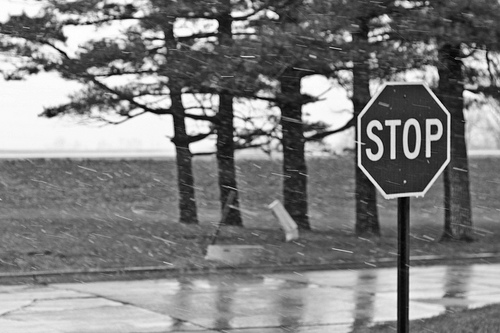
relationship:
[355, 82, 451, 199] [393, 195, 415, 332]
border on pole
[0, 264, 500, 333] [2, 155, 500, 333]
crack on grass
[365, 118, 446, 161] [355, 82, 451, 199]
caps on border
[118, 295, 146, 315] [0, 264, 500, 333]
crack in crack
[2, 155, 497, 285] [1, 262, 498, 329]
grass on ground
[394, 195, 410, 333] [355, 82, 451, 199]
pole holding up border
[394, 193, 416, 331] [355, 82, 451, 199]
pole holding border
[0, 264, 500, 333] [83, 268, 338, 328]
crack on ground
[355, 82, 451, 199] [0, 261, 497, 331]
border on a street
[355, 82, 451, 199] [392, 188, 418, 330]
border on pole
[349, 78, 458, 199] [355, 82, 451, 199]
border around border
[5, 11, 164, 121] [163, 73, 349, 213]
branches sticking out from trunk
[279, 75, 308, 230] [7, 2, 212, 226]
trunk of tree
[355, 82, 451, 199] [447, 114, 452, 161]
border has white perimeter